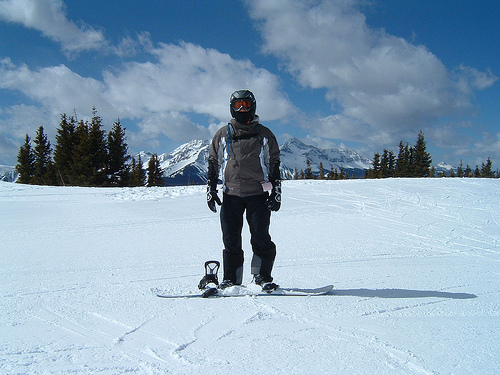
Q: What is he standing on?
A: Snowboard.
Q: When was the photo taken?
A: Day time.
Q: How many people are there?
A: One.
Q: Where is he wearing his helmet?
A: Head.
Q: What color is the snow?
A: White.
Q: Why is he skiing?
A: For fun.